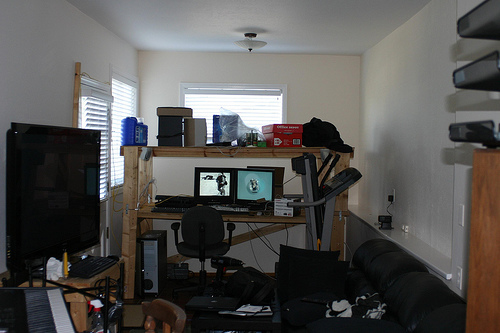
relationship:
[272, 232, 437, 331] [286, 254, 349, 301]
couch has pillows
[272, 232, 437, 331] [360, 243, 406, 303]
couch has cushion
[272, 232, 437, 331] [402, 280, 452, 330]
couch has cushion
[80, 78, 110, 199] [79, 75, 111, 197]
blinds have set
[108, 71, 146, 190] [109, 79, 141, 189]
blinds have set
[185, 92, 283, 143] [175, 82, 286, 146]
blinds have set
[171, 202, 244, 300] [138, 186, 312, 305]
chair near desk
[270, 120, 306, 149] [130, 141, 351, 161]
box on top of shelf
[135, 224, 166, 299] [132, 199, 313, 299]
tower under desk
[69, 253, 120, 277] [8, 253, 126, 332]
keyboard on table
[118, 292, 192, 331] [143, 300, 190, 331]
chair has top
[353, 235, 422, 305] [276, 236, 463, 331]
cushion on top of couch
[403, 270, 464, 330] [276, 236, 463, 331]
cushion on top of couch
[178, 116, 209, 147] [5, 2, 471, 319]
clutter in room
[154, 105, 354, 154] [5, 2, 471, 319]
clutter in room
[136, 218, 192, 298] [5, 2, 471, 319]
clutter in room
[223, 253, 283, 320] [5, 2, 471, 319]
clutter in room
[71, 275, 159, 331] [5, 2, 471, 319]
clutter in room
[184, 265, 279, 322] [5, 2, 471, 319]
clutter in room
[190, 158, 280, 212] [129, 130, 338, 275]
monitors on desk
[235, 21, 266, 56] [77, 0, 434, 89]
light on ceiling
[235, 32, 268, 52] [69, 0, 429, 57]
light on ceiling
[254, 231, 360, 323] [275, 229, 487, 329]
pillows on couch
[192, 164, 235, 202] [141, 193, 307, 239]
monitor on a desk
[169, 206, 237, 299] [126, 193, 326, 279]
chair in front of desk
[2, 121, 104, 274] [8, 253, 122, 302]
television on a table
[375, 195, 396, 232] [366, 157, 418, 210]
an apparatus plugged into wall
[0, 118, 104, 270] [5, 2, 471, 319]
television on right side of room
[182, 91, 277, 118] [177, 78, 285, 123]
blinds in front window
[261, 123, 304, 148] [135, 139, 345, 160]
box on shelf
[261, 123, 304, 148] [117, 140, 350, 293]
box on cabinet